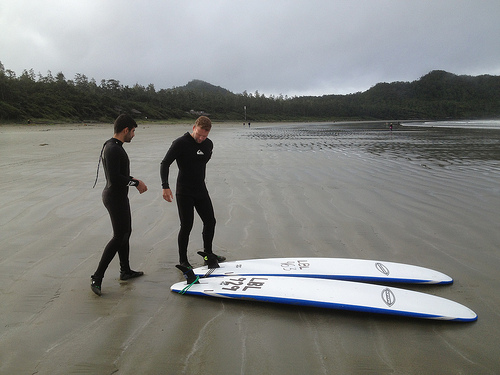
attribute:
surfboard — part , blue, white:
[171, 260, 481, 327]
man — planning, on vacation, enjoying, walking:
[158, 114, 231, 277]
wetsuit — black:
[159, 130, 220, 263]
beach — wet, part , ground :
[3, 119, 500, 374]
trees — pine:
[53, 71, 67, 85]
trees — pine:
[108, 78, 120, 91]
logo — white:
[196, 148, 206, 157]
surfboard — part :
[182, 249, 455, 288]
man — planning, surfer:
[85, 111, 157, 301]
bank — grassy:
[2, 104, 379, 127]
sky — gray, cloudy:
[2, 1, 498, 96]